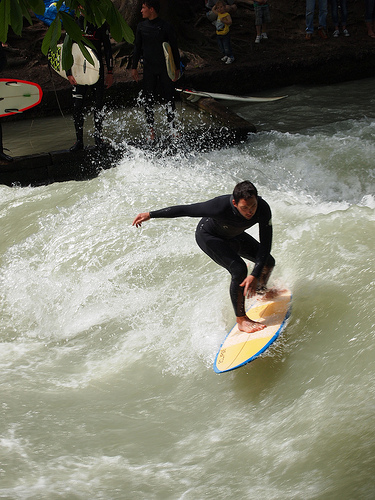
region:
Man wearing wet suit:
[212, 189, 257, 293]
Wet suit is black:
[210, 237, 280, 302]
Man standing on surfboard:
[212, 274, 277, 366]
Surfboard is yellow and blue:
[211, 307, 266, 364]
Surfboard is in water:
[202, 288, 294, 398]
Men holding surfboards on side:
[59, 20, 203, 105]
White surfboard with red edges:
[16, 49, 40, 129]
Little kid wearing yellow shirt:
[216, 9, 237, 58]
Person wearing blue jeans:
[301, 6, 328, 25]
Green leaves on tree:
[24, 17, 141, 62]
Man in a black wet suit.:
[79, 159, 283, 307]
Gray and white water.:
[21, 420, 284, 499]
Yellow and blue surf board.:
[170, 275, 295, 386]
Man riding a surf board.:
[68, 166, 280, 385]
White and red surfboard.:
[172, 78, 306, 118]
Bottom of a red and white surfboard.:
[0, 49, 58, 136]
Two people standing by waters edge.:
[14, 0, 231, 194]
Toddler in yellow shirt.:
[202, 0, 258, 72]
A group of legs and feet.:
[238, 0, 373, 51]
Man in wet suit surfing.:
[50, 114, 367, 480]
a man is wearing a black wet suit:
[149, 193, 272, 315]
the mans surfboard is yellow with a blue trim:
[214, 286, 292, 373]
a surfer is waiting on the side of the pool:
[127, 1, 180, 145]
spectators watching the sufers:
[211, 0, 373, 65]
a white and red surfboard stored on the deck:
[175, 87, 286, 101]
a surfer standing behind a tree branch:
[46, 1, 114, 153]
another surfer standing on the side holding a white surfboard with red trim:
[0, 76, 41, 164]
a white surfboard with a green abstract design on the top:
[46, 41, 100, 86]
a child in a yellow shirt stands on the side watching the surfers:
[212, 1, 233, 65]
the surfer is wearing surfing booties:
[68, 130, 83, 151]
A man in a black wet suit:
[130, 186, 295, 326]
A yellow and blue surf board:
[215, 293, 294, 390]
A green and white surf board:
[44, 33, 101, 86]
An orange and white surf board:
[2, 64, 47, 134]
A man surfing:
[137, 171, 314, 383]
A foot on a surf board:
[204, 305, 284, 382]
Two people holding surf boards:
[50, 7, 185, 151]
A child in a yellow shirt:
[206, 7, 240, 67]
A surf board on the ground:
[172, 82, 304, 126]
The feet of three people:
[250, 21, 360, 48]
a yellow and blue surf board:
[214, 281, 295, 382]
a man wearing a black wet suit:
[167, 181, 289, 339]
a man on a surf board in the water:
[125, 167, 316, 391]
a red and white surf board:
[4, 69, 48, 147]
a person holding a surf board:
[47, 10, 110, 164]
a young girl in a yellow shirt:
[195, 6, 240, 47]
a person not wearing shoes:
[232, 245, 280, 346]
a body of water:
[20, 254, 142, 487]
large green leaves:
[23, 15, 151, 85]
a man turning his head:
[135, 4, 165, 31]